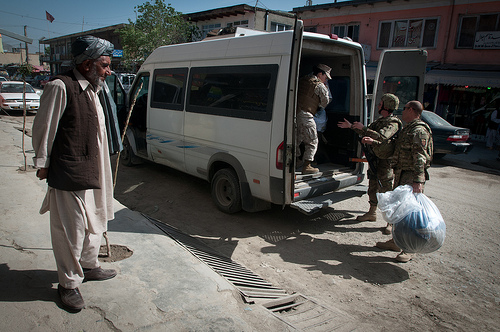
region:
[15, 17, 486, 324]
American soldiers are stationed in Kabul.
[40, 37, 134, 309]
An Afghan man in ethnic clothing.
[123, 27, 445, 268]
American soldiers standing near a van.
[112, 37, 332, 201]
Blue and white van.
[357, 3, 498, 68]
Old red brick building.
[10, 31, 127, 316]
A man appeared to be amused.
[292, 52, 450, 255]
Soldiers loading donated goods.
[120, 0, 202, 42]
A tree in the background.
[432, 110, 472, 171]
A green sedan in the background.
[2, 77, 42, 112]
A white sedan parking in front of the van.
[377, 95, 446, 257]
person standing near a van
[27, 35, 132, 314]
person standing near a van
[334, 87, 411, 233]
person standing near a van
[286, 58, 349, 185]
person standing in a van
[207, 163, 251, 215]
tire on a van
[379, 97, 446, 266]
person wearing military uniform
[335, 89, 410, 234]
person wearing military uniform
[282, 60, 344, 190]
person wearing military uniform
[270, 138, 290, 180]
tail light on a van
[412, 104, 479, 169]
car parked on the street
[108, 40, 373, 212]
The white van the soldiers are taking bags out of.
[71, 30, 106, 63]
The headwrap on the man's head.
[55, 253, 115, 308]
The brown shoes the man on the sidewalk is wearing.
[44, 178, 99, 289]
The beige pants the man on the sidewalk is wearing.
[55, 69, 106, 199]
The brown vest the man on the sidewalk is wearing.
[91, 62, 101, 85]
The gray beard of the man on the sidewalk.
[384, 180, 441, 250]
The plastic bag in the soldier's hand.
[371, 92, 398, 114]
The helmet on the soldier's head.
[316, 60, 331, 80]
The hat the soldier is wearing inside of the van.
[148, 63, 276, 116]
The side windows of the white van.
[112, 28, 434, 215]
white van with doors open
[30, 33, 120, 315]
man in brown standing on the sidewalk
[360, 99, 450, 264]
soldier holding plastic bag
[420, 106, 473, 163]
black car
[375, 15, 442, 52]
window of building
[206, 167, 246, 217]
black tire of van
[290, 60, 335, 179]
soldier loading bags out of van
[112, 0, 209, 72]
top of green tree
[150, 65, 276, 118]
side windows of van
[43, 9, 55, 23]
flag flying in the background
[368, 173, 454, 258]
a plastic bag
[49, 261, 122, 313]
brown shoes on the ground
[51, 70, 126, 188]
a dark brown vest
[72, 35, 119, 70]
a man wearing a turban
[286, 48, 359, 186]
a man unloading a van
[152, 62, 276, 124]
a window on the van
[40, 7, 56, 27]
a flag in the sky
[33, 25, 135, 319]
a man on the side of the road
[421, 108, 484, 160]
back of a green car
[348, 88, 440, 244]
two men in uniform